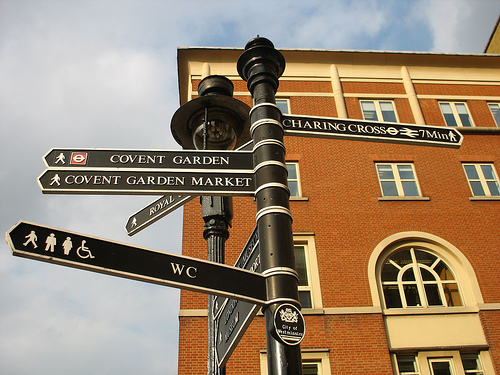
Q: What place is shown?
A: It is a city.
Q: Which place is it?
A: It is a city.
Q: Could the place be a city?
A: Yes, it is a city.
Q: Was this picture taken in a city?
A: Yes, it was taken in a city.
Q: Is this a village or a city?
A: It is a city.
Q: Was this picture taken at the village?
A: No, the picture was taken in the city.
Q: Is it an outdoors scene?
A: Yes, it is outdoors.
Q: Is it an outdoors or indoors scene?
A: It is outdoors.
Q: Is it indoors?
A: No, it is outdoors.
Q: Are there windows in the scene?
A: Yes, there is a window.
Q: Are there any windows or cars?
A: Yes, there is a window.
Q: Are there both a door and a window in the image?
A: No, there is a window but no doors.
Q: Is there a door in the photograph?
A: No, there are no doors.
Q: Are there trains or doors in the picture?
A: No, there are no doors or trains.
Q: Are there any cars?
A: No, there are no cars.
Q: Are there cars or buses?
A: No, there are no cars or buses.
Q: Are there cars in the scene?
A: No, there are no cars.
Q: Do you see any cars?
A: No, there are no cars.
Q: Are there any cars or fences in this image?
A: No, there are no cars or fences.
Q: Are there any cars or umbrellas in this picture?
A: No, there are no cars or umbrellas.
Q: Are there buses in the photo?
A: No, there are no buses.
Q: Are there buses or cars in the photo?
A: No, there are no buses or cars.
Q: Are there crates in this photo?
A: No, there are no crates.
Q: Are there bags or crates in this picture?
A: No, there are no crates or bags.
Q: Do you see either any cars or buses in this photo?
A: No, there are no cars or buses.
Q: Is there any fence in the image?
A: No, there are no fences.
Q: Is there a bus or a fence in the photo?
A: No, there are no fences or buses.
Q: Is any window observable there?
A: Yes, there is a window.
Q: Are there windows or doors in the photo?
A: Yes, there is a window.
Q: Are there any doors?
A: No, there are no doors.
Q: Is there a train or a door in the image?
A: No, there are no doors or trains.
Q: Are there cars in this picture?
A: No, there are no cars.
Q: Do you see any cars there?
A: No, there are no cars.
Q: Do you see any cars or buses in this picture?
A: No, there are no cars or buses.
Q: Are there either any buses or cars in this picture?
A: No, there are no cars or buses.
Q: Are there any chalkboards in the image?
A: No, there are no chalkboards.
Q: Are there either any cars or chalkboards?
A: No, there are no chalkboards or cars.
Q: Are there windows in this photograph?
A: Yes, there is a window.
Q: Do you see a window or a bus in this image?
A: Yes, there is a window.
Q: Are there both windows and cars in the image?
A: No, there is a window but no cars.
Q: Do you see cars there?
A: No, there are no cars.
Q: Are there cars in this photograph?
A: No, there are no cars.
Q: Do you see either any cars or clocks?
A: No, there are no cars or clocks.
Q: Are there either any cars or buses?
A: No, there are no cars or buses.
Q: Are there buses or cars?
A: No, there are no cars or buses.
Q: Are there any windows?
A: Yes, there is a window.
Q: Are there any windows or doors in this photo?
A: Yes, there is a window.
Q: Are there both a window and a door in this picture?
A: No, there is a window but no doors.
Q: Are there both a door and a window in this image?
A: No, there is a window but no doors.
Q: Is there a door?
A: No, there are no doors.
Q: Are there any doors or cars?
A: No, there are no doors or cars.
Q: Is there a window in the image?
A: Yes, there is a window.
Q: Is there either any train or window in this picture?
A: Yes, there is a window.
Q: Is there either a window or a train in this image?
A: Yes, there is a window.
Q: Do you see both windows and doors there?
A: No, there is a window but no doors.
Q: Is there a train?
A: No, there are no trains.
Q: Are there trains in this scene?
A: No, there are no trains.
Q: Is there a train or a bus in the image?
A: No, there are no trains or buses.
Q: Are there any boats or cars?
A: No, there are no cars or boats.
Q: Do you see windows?
A: Yes, there is a window.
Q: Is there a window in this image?
A: Yes, there is a window.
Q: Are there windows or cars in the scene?
A: Yes, there is a window.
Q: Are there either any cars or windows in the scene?
A: Yes, there is a window.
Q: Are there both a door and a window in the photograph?
A: No, there is a window but no doors.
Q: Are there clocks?
A: No, there are no clocks.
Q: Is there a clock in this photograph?
A: No, there are no clocks.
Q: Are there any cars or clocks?
A: No, there are no clocks or cars.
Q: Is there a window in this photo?
A: Yes, there is a window.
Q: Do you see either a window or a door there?
A: Yes, there is a window.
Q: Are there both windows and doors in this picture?
A: No, there is a window but no doors.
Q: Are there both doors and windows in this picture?
A: No, there is a window but no doors.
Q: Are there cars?
A: No, there are no cars.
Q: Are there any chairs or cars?
A: No, there are no cars or chairs.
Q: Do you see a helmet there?
A: No, there are no helmets.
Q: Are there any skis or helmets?
A: No, there are no helmets or skis.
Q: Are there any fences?
A: No, there are no fences.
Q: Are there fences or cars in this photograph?
A: No, there are no fences or cars.